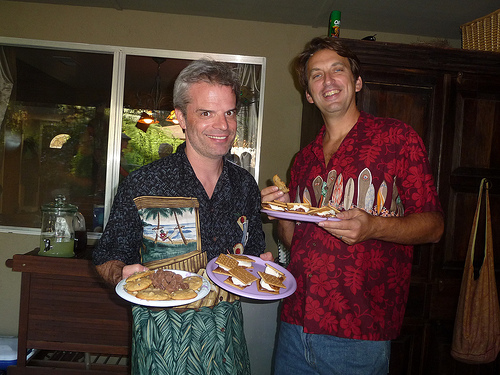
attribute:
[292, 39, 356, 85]
hair — brown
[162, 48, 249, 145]
hair — gray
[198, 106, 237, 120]
eyes — brown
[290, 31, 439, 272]
hair — brown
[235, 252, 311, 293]
plate — purple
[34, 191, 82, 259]
container — glass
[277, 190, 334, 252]
plate — full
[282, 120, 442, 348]
shirt — red , floral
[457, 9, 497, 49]
basket — woven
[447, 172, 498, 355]
purse — light brown 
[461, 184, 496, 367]
orange purse — big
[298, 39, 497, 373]
cupboard — tall, wooden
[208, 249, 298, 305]
plate — purple 